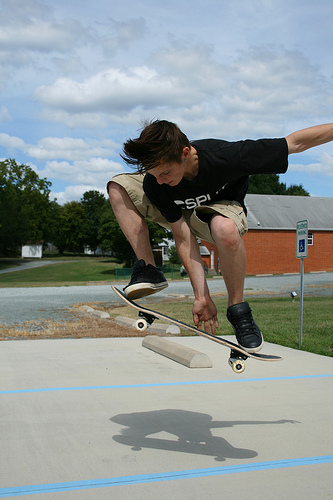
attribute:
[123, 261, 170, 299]
shoe — black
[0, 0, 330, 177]
sky — bright blue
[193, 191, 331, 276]
building — red brick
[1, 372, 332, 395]
stripe — blue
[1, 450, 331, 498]
stripe — blue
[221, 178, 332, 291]
building — red, brick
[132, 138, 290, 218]
shirt — black